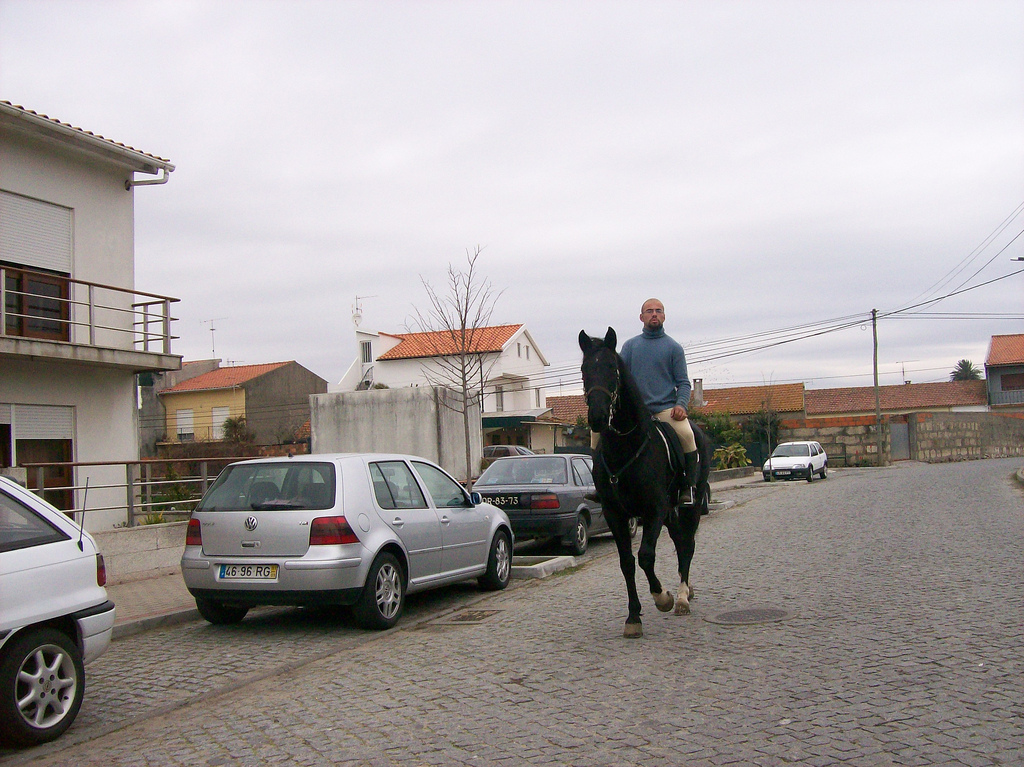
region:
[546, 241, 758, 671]
a man on a horse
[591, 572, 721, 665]
the horse has white hooves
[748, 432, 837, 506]
the car is white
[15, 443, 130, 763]
the back of a car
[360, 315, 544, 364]
red roof on a house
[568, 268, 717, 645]
the man is wearing tan pants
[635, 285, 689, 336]
the man is bald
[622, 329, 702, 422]
sweater on man is blue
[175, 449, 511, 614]
car on street is grey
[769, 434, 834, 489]
car facing camera is white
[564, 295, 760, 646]
man is on horese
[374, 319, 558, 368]
roof on house is red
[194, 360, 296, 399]
roof on yellow house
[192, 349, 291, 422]
roof is red on yellow house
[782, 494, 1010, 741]
street is grey colored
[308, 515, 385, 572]
taillight on grey car is red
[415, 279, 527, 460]
tree has no leaves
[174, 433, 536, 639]
The silver VW car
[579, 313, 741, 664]
the black horse the man is riding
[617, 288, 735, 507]
the man riding the horse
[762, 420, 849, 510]
the farthest away white car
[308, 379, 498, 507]
The square cement block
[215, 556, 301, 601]
The license plate of the VW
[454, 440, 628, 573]
The grey car hidden by the horse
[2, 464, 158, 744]
the only showing part of the white car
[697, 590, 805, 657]
the manhole cover in the road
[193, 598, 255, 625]
car has a black tire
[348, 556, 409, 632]
car has a black tire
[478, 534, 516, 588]
car has a black tire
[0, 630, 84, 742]
car has a black tire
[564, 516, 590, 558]
car has a black tire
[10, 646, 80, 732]
tire has a metal rim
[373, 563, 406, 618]
tire has a metal rim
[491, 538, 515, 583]
tire has a metal rim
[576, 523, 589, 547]
tire has a metal rim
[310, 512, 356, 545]
car has a tail light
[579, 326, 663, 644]
Black horse trotting down street with man on it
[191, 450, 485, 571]
light Grey car parked on side ot tan colored building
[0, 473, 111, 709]
Backside of white car that is behind the light grey car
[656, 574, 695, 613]
Horses white hoofs walking on street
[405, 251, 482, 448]
skinny bare tree on the left side of dark colored car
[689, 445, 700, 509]
Black riding boots man on the horse is wearing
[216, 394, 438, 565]
a vehicle ont he road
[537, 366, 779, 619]
a horse on the road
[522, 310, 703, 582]
a man riding a horse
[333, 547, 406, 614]
a tire on the vehicle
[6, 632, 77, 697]
a tire on the vehicle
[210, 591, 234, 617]
a tire on the vehicle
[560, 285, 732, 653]
A man riding a black horse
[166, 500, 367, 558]
Two red rear lights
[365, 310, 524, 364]
The roof of a building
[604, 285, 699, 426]
Man wearing a blue sweater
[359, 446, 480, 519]
Side windows of a car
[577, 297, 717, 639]
Man riding a black horse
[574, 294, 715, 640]
Bald man riding a black horse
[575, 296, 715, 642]
Man in blue sweater riding a horse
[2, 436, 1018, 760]
Cars parked on the side of the road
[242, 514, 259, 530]
Silver volkswagen logo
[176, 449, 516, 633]
Car with volkswagen logo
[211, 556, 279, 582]
White license plate